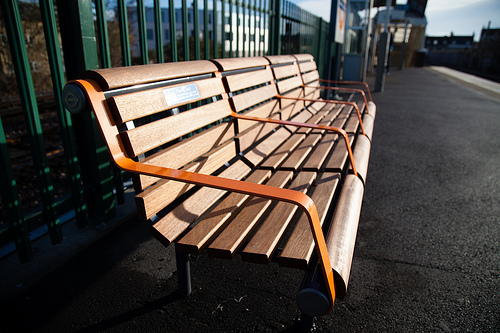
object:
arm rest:
[230, 110, 357, 175]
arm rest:
[319, 79, 373, 102]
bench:
[62, 54, 376, 333]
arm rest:
[300, 84, 368, 114]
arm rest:
[69, 80, 332, 282]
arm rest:
[274, 94, 365, 134]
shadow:
[23, 237, 183, 330]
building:
[117, 0, 303, 62]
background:
[4, 3, 495, 118]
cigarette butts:
[212, 295, 247, 314]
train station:
[316, 4, 431, 88]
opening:
[372, 11, 411, 71]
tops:
[427, 21, 497, 39]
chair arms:
[301, 85, 370, 112]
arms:
[220, 93, 356, 175]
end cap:
[297, 288, 330, 316]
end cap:
[62, 84, 86, 114]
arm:
[60, 79, 337, 307]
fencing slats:
[3, 0, 62, 247]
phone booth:
[340, 0, 389, 92]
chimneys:
[450, 31, 453, 36]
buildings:
[413, 17, 499, 80]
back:
[95, 59, 320, 216]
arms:
[274, 93, 365, 135]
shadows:
[174, 173, 342, 223]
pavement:
[6, 67, 499, 329]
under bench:
[3, 199, 319, 329]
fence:
[4, 0, 328, 276]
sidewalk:
[351, 58, 484, 330]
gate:
[3, 2, 335, 255]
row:
[188, 70, 370, 309]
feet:
[178, 283, 193, 296]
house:
[423, 31, 478, 61]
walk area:
[0, 64, 497, 328]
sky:
[426, 1, 497, 39]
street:
[6, 59, 496, 326]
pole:
[375, 32, 391, 92]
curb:
[426, 62, 497, 95]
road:
[4, 66, 495, 328]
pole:
[175, 246, 192, 297]